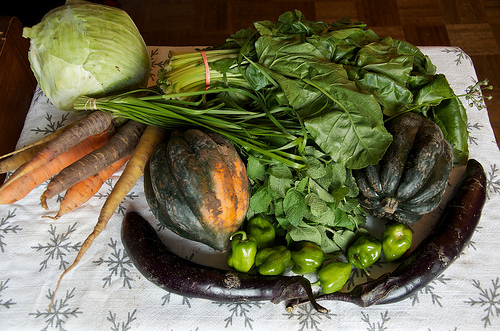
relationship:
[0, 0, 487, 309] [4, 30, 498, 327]
vegetable on sheet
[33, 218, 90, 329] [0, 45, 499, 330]
design on cloth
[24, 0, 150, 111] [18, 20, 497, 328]
cabbage on table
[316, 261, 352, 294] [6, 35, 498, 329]
bonnet pepper on towel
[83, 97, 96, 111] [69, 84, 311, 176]
band on stock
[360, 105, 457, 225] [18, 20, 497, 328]
squash on table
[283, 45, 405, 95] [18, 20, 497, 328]
lettuce on table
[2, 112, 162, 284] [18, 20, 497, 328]
carrots on table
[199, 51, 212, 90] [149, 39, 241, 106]
pink band on stock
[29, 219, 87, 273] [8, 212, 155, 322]
snowflake on towel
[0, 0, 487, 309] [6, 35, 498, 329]
vegetable on towel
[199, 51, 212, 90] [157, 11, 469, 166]
pink band on bunch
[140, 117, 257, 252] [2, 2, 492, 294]
corn on top of table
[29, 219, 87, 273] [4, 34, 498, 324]
snowflake on top of tablecloth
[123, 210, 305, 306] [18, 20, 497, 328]
eggplant on top of table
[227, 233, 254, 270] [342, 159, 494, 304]
bonnet pepper next to eggplant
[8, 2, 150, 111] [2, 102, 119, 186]
cabbage next to carrot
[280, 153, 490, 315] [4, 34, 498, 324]
eggplant on top of tablecloth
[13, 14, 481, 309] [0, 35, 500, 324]
vegetable on cloth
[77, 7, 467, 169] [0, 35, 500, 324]
green leaves on cloth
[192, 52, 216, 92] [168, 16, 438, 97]
pink band around vegetables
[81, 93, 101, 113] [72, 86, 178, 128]
band on stems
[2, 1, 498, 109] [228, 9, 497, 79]
floor on wood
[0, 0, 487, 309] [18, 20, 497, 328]
vegetable on table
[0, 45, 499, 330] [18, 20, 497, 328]
cloth on top of table